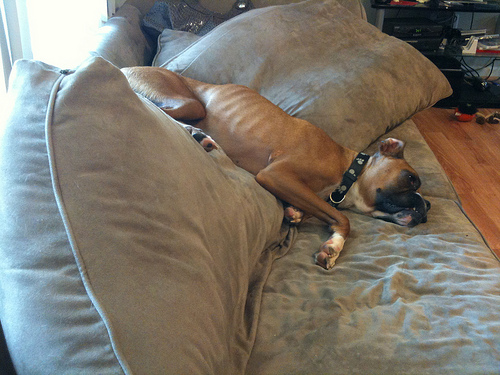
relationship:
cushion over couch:
[155, 0, 454, 151] [0, 1, 499, 373]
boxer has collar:
[118, 65, 430, 270] [328, 150, 373, 205]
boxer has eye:
[118, 65, 430, 270] [403, 168, 418, 189]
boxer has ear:
[118, 65, 430, 270] [377, 131, 412, 162]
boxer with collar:
[118, 65, 430, 270] [325, 148, 370, 210]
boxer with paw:
[118, 65, 430, 270] [187, 124, 220, 153]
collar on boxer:
[328, 150, 373, 205] [118, 65, 430, 270]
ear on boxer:
[380, 136, 407, 161] [138, 71, 430, 258]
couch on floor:
[0, 1, 499, 373] [412, 102, 498, 247]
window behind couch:
[21, 2, 102, 69] [47, 31, 306, 286]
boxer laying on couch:
[118, 65, 430, 270] [0, 1, 499, 373]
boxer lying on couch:
[118, 65, 430, 270] [0, 1, 499, 373]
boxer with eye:
[118, 65, 430, 270] [406, 178, 420, 187]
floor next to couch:
[411, 105, 495, 257] [71, 13, 468, 368]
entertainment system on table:
[366, 1, 496, 108] [433, 0, 485, 78]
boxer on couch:
[122, 65, 434, 271] [0, 1, 499, 373]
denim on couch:
[138, 1, 253, 52] [25, 265, 495, 367]